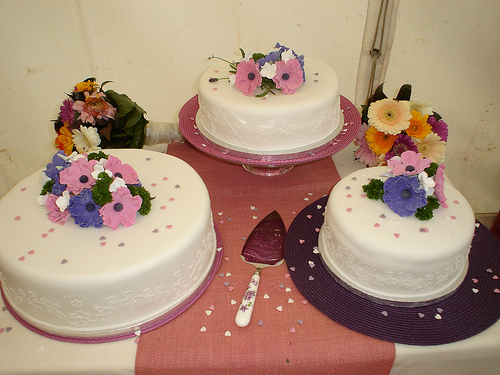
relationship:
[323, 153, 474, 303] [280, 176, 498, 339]
cake on mat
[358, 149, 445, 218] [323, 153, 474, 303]
flowers on cake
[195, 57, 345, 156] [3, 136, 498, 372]
cake on table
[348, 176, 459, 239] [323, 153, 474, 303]
sprinkles on cake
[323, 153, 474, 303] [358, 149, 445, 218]
cake has flowers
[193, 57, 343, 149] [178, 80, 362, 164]
cake on plate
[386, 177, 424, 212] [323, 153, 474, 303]
flower on cake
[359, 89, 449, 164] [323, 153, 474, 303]
flowers next to cake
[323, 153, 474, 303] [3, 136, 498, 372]
cake on table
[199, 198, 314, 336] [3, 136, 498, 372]
confetti on table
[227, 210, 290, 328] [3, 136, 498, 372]
spatula on table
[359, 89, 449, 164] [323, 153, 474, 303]
flowers near cake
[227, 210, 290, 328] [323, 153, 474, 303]
spatula for cake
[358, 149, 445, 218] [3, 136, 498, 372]
flowers on table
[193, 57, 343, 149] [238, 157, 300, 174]
cake on stand